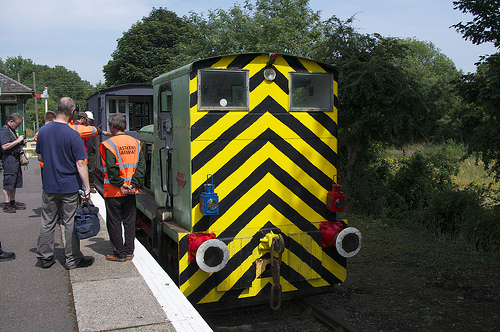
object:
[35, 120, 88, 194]
shirt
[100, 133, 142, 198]
vest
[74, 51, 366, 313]
train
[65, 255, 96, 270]
shoe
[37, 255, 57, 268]
shoe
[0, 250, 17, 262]
shoe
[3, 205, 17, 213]
shoe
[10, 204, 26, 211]
shoe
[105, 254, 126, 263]
shoe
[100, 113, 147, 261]
man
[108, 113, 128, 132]
hair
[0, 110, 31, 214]
man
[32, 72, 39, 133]
pole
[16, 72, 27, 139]
pole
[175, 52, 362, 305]
back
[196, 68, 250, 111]
window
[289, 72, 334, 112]
window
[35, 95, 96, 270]
man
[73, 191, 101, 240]
pack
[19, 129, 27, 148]
camera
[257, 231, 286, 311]
hitch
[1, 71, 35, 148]
building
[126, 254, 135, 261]
shoe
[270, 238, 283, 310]
chain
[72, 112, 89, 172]
man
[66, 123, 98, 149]
vest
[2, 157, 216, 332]
platform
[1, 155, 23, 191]
shorts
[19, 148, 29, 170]
pack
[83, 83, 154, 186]
car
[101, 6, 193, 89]
tree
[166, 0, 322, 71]
tree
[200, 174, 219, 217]
lantern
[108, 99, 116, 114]
window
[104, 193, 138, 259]
pants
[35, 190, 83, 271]
pants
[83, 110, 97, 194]
man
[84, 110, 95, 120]
helmet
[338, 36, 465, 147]
tree